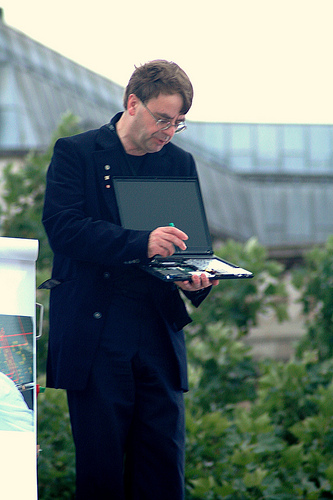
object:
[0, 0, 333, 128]
sky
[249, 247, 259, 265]
leaves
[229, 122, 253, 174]
glass panel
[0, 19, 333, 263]
structure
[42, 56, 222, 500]
man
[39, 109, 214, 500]
suit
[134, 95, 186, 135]
glasses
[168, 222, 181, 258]
tool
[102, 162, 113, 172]
pin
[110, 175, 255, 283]
laptop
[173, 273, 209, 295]
hand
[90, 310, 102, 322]
pin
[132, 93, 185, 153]
face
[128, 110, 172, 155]
five o'clock shadow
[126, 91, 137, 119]
ear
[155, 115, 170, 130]
eyes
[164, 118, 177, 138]
nose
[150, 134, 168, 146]
mouth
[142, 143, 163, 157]
chin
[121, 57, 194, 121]
hair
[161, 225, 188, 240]
fingers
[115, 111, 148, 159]
neck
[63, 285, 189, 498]
pants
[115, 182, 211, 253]
screen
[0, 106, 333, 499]
trees